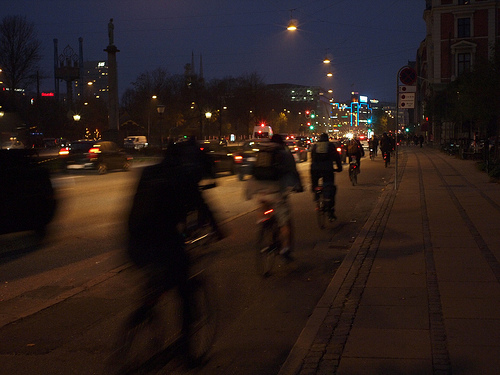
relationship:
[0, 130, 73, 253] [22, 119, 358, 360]
cars on road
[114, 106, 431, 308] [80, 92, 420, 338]
people riding bikes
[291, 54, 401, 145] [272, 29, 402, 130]
lights in building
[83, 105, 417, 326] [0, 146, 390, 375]
people biking in road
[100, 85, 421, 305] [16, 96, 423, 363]
people biking in street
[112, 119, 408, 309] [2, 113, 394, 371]
people biking in street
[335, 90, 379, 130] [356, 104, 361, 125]
building with lights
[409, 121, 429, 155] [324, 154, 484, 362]
people on sidewalk